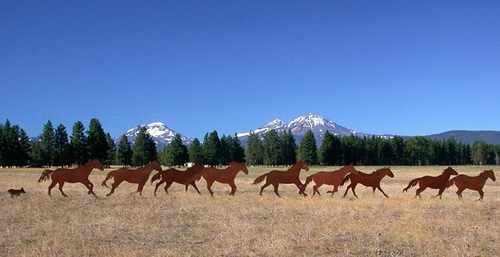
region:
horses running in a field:
[36, 146, 498, 208]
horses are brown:
[36, 154, 498, 200]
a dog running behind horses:
[5, 180, 28, 202]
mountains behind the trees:
[119, 103, 487, 139]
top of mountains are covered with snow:
[119, 109, 359, 145]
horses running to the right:
[33, 155, 498, 200]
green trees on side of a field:
[3, 114, 490, 169]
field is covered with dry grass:
[0, 163, 497, 254]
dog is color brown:
[5, 180, 30, 201]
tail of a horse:
[34, 163, 58, 186]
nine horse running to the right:
[36, 154, 497, 202]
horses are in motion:
[39, 153, 496, 202]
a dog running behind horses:
[4, 157, 498, 199]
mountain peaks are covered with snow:
[120, 109, 356, 131]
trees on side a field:
[4, 116, 498, 167]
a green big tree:
[82, 114, 114, 163]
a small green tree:
[185, 134, 205, 165]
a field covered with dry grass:
[5, 196, 498, 254]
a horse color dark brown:
[399, 160, 463, 202]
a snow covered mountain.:
[231, 95, 366, 140]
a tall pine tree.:
[127, 122, 165, 166]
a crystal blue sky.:
[0, 0, 498, 141]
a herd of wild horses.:
[34, 151, 495, 203]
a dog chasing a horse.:
[4, 179, 32, 208]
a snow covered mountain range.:
[92, 119, 497, 160]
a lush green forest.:
[0, 112, 496, 176]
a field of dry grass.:
[1, 163, 498, 248]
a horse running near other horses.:
[339, 160, 399, 203]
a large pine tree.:
[84, 110, 112, 170]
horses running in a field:
[26, 58, 497, 217]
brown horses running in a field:
[32, 72, 477, 255]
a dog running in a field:
[5, 172, 89, 207]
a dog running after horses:
[5, 118, 453, 255]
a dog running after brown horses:
[4, 122, 495, 254]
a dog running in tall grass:
[4, 118, 497, 240]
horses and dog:
[1, 90, 491, 233]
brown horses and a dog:
[9, 101, 497, 250]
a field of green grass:
[17, 93, 479, 255]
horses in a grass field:
[12, 91, 496, 238]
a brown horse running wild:
[53, 168, 80, 183]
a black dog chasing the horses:
[9, 186, 29, 194]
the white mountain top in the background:
[263, 116, 280, 125]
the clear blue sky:
[362, 31, 417, 76]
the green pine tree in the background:
[80, 117, 110, 142]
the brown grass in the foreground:
[263, 215, 314, 255]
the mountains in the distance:
[455, 124, 474, 134]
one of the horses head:
[378, 162, 395, 180]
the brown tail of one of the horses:
[251, 173, 262, 183]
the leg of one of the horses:
[261, 185, 266, 195]